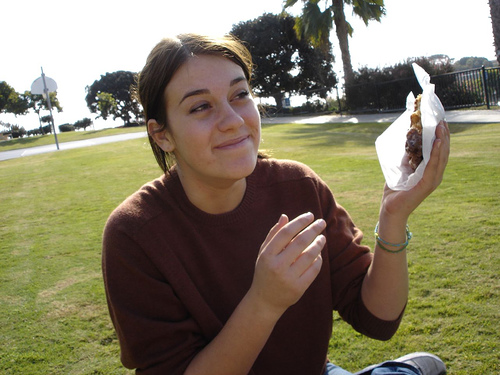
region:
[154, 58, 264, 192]
a girl's face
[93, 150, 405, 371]
a dark brown sweater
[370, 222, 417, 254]
a pair of a blue and green braclet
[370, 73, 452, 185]
yummy looking food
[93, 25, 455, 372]
a girl sitting in grass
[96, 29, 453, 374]
a younge girl eating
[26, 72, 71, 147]
a white basketball hoop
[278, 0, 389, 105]
a tall palm tree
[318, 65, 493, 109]
a black iron fence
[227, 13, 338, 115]
a short very bushy tree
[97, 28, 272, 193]
woman is smiling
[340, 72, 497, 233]
woman holding some food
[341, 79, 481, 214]
food is in paper wrapper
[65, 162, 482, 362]
woman's shirt is brown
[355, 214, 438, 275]
woman wearing some bracelets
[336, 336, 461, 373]
woman's shoe is white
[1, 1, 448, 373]
woman is sitting in grass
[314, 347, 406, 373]
woman is wearing blue jeans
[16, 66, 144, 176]
sign behind the woman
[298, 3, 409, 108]
palm tree behind the woman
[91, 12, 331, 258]
this girl looks happy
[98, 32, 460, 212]
she is smiling at her food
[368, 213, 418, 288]
she is wearing blue & green bracelets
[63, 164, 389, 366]
the girl is wearing a brown sweater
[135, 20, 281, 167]
the girl has brown hair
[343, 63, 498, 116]
the fence in back is black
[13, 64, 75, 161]
a basketball backstop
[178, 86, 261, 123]
the girl has dark eyes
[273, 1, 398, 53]
palm trees are in the background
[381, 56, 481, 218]
whatever the food is it's wrapped in paper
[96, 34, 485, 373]
the woman holding the hotdog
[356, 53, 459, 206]
the hotdog wrapped in wax paper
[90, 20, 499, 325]
the woman is smiling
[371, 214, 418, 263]
the bracelet on the wrist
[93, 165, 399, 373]
the sweater is burgundy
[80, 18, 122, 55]
the clear blue sky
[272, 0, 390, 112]
the palm tree beside the fence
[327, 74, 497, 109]
the fence is black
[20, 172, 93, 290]
the grass is well groomed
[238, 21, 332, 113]
tree with green leaves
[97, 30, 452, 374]
a girl sitting on grass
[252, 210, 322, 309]
a woman's right hand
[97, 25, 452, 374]
A girl eating something yummy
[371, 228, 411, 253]
a pair of braclets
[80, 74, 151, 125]
a large tree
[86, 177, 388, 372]
a woman's dark sweater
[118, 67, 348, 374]
a woman smiling for a photo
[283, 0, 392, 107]
a very tall palm tree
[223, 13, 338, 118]
a short full bushy tree